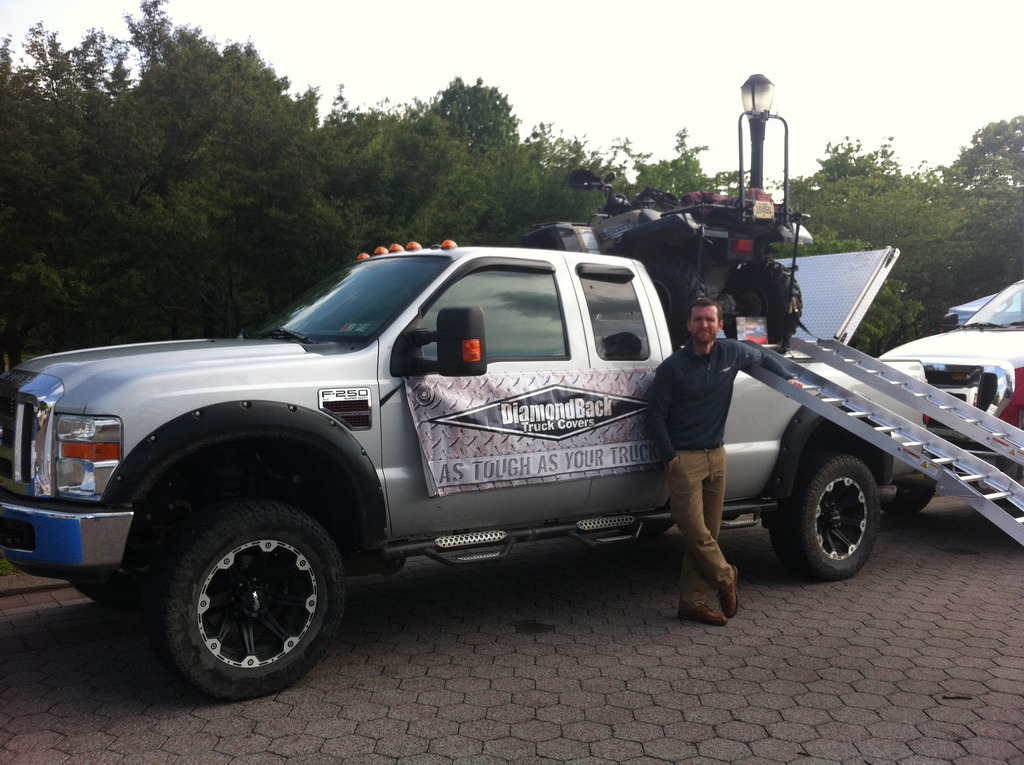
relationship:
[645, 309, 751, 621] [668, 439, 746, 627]
he wearing pants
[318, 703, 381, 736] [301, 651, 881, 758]
tile in floor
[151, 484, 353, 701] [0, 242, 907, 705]
tire on truck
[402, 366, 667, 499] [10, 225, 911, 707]
banner on side of truck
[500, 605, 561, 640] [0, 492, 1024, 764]
stain on floor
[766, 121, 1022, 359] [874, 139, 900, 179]
trees with leaves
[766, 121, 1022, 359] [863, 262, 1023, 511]
trees behind suv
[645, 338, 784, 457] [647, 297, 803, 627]
shirt on a he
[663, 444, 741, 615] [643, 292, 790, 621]
pants on a man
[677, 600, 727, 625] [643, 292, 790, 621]
shoe on a man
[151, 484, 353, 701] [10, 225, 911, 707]
tire on a truck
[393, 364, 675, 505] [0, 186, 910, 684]
banner on side of a truck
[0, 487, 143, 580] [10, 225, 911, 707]
bumper on a truck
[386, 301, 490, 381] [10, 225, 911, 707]
mirror on a truck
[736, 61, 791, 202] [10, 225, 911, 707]
street light behind a truck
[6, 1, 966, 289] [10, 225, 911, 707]
trees behind truck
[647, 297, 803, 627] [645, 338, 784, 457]
he in a shirt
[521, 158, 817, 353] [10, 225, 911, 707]
four wheeler in truck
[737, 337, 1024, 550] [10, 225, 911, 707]
ramp on truck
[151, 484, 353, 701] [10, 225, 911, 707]
tire on truck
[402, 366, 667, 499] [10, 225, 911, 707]
banner on truck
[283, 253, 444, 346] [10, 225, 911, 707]
windshield on truck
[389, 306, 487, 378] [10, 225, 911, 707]
mirror on truck